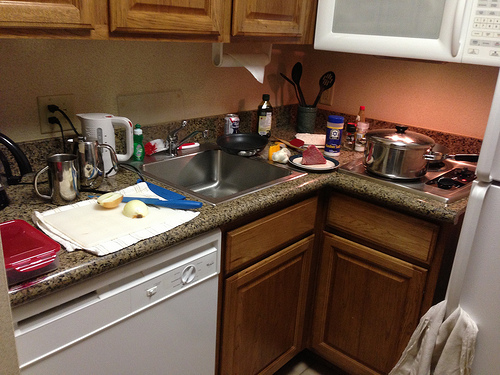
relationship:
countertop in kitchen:
[0, 103, 496, 288] [1, 2, 498, 353]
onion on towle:
[93, 180, 157, 227] [37, 181, 189, 247]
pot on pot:
[360, 120, 442, 184] [360, 120, 479, 184]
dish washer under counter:
[10, 222, 225, 374] [10, 248, 116, 298]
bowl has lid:
[8, 258, 55, 288] [0, 218, 63, 271]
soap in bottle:
[116, 110, 156, 171] [121, 110, 158, 173]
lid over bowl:
[3, 212, 75, 282] [0, 218, 62, 287]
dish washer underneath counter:
[10, 227, 222, 374] [4, 104, 484, 307]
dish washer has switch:
[10, 227, 222, 374] [145, 283, 161, 298]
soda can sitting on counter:
[222, 110, 240, 137] [0, 120, 472, 306]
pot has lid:
[360, 120, 479, 184] [362, 121, 437, 151]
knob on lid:
[391, 120, 411, 135] [362, 121, 437, 151]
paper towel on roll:
[212, 45, 281, 81] [208, 38, 274, 70]